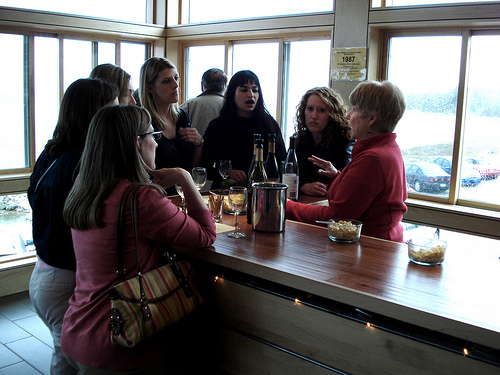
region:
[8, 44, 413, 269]
a group of women are having a conversation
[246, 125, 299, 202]
wine bottles are on the counter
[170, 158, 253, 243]
wine glasses are on the counter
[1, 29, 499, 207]
the room has several windows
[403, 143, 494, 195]
cars are parked outside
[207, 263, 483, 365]
lights are under the bar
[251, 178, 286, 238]
a chilling bucket sits on the counter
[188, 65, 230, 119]
this woman is looking out of the window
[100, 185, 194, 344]
she is holding onto her purse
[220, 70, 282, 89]
this woman's bangs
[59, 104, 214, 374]
woman standing next to bar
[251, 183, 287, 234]
silver ice bucket on top of bar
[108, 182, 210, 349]
woman holding a striped purse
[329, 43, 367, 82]
yellow laminated sign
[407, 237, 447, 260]
glass bowl on top of bar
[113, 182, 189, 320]
leather straps attached to purse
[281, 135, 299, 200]
glass wine bottle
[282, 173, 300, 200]
white label attached to wine bottle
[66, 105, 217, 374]
woman wearing glasses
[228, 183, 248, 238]
wine glass is empty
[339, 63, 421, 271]
Woman standing at a table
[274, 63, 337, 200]
Woman standing at a table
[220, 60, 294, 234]
Woman standing at a table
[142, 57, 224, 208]
Woman standing at a table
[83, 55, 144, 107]
Woman standing at a table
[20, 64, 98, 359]
Woman standing at a table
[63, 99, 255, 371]
Woman standing at a table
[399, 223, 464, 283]
Clear bowl of food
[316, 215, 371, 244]
Clear bowl of food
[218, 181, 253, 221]
Clear bowl of food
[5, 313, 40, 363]
the floor is tiled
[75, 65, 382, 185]
the group of women are talking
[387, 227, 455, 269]
the bowl of nuts on the counter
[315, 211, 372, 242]
the bowl of nuts on the counter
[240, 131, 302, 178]
the bottles of wine on the counter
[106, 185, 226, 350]
the handbag on the shoulder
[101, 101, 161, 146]
the woman wearing glasses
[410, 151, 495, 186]
the cars outside are parked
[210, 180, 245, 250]
the glass on the counter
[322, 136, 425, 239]
the woman wearing the red jacket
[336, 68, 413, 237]
Woman standing at the table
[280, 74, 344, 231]
Woman standing at the table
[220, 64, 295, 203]
Woman standing at the table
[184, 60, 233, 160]
Woman standing at the table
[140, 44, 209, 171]
Woman standing at the table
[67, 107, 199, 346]
Woman standing at the table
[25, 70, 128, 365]
Woman standing at the table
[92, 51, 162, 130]
Woman standing at the table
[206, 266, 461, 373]
Lights under a bar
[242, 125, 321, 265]
Bottles of wine on a bar